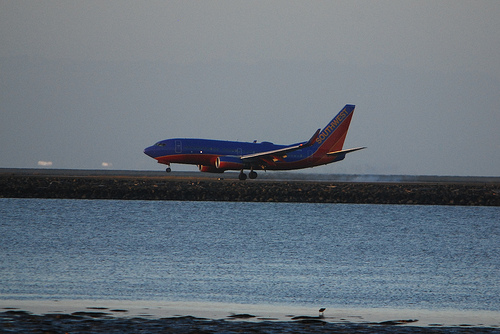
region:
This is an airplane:
[122, 100, 375, 167]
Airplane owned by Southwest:
[131, 100, 375, 174]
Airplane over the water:
[10, 93, 492, 298]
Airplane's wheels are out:
[151, 160, 268, 185]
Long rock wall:
[45, 170, 485, 209]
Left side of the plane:
[122, 98, 376, 188]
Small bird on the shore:
[307, 297, 331, 318]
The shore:
[4, 301, 494, 331]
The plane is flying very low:
[132, 103, 386, 188]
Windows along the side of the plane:
[172, 136, 314, 160]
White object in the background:
[99, 157, 113, 170]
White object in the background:
[35, 157, 52, 169]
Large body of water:
[2, 197, 498, 311]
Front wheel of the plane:
[163, 161, 174, 175]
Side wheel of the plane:
[236, 167, 260, 182]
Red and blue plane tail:
[317, 97, 355, 149]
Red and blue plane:
[141, 100, 365, 178]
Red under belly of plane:
[148, 155, 348, 170]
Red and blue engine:
[214, 150, 262, 169]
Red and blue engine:
[194, 159, 222, 171]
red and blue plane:
[143, 103, 364, 172]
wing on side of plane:
[241, 140, 306, 160]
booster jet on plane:
[215, 155, 242, 170]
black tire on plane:
[164, 165, 171, 173]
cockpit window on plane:
[154, 140, 167, 145]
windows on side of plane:
[203, 143, 252, 153]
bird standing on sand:
[318, 306, 325, 316]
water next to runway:
[1, 195, 498, 316]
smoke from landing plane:
[302, 169, 404, 184]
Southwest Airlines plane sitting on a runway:
[145, 97, 369, 187]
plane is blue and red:
[140, 100, 365, 179]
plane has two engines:
[196, 154, 250, 176]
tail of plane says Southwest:
[303, 100, 366, 164]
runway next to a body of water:
[4, 159, 498, 216]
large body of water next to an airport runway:
[1, 187, 497, 332]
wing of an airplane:
[240, 126, 327, 171]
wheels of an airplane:
[159, 162, 263, 184]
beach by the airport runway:
[2, 285, 497, 332]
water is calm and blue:
[4, 185, 496, 318]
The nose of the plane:
[143, 147, 148, 152]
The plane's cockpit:
[156, 142, 166, 148]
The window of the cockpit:
[157, 142, 160, 143]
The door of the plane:
[175, 140, 180, 150]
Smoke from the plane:
[358, 175, 374, 178]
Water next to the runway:
[185, 202, 235, 222]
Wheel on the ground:
[247, 170, 254, 175]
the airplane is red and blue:
[145, 103, 369, 181]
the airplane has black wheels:
[144, 104, 368, 179]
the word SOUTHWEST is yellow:
[315, 107, 351, 144]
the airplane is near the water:
[1, 103, 498, 310]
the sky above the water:
[1, 0, 499, 311]